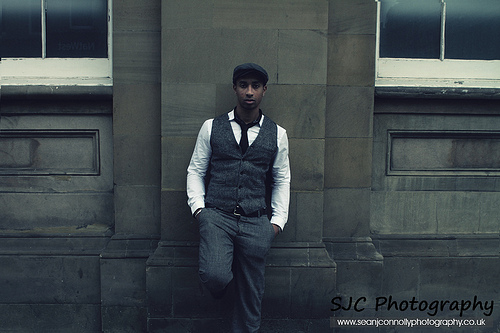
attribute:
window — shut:
[375, 0, 499, 88]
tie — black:
[232, 103, 263, 151]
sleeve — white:
[184, 116, 213, 214]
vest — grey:
[205, 111, 277, 215]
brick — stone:
[276, 27, 331, 84]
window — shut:
[375, 3, 497, 80]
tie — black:
[235, 123, 252, 149]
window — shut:
[3, 0, 119, 89]